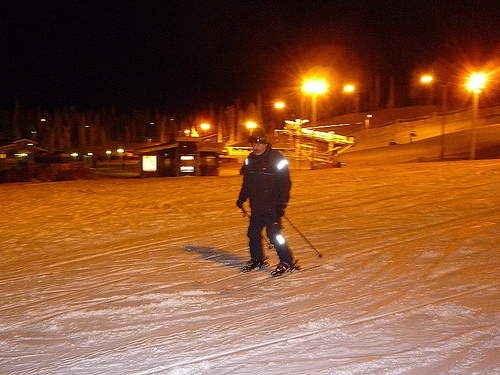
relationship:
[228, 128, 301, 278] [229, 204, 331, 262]
man holding poles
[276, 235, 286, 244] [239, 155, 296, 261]
bright light are on cloths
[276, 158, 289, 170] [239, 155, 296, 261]
light are on cloths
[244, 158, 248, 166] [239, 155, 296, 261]
reflective material are on cloths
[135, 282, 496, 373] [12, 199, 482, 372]
tracks are snow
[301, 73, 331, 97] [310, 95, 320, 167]
lights are on pole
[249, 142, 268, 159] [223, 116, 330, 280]
beard on man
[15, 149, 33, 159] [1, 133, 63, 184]
window on building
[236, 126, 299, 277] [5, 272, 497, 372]
man skiing in snow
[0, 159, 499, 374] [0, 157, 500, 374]
snow covering field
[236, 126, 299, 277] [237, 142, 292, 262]
man wearing cloths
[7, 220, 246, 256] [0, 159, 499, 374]
tracks in snow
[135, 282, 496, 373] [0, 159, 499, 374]
tracks in snow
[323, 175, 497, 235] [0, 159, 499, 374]
tracks in snow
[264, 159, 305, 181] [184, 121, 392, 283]
light on man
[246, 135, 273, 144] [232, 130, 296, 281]
hat on man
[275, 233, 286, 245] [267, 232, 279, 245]
bright light on knee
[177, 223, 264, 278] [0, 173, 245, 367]
shadow in snow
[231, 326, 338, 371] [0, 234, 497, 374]
white snow covers ground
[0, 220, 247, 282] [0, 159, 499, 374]
tracks in snow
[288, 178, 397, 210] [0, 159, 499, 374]
tracks in snow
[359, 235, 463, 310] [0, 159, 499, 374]
tracks in snow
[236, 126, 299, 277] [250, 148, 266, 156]
man has beard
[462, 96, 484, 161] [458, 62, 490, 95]
pole with light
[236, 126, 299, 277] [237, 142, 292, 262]
man wears cloths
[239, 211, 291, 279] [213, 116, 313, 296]
legs of person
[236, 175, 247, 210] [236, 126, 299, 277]
arm of man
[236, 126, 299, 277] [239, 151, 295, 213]
man wearing jacket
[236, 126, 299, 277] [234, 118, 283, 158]
man wearing hat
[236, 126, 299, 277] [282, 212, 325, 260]
man holding poles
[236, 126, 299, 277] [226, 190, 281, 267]
man holding sticks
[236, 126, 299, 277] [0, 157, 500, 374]
man skiing down a field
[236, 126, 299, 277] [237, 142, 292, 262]
man wearing a cloths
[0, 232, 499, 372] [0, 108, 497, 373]
ski prints in snow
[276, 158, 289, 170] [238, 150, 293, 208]
light on shoulder of a jacket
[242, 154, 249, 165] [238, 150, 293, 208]
reflective material on shoulder of a jacket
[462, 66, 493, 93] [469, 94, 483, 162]
light on a pole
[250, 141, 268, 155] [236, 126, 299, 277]
head of a man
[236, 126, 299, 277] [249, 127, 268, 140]
man wearing a hat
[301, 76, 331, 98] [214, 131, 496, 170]
lights on street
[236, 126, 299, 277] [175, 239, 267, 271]
man casting shadow